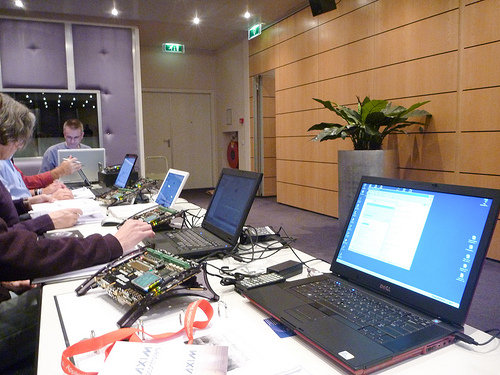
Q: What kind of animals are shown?
A: None.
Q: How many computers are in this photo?
A: Five.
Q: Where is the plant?
A: Against the wall.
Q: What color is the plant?
A: Green.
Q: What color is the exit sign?
A: Green.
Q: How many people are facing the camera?
A: One.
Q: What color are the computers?
A: Black & white.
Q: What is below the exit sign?
A: Doors.